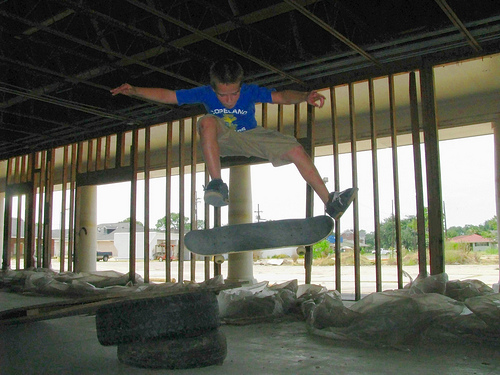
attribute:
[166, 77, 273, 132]
t-shirt — blue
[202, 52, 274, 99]
hair — short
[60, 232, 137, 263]
truck — parked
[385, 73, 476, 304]
stud — wooden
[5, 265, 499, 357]
sheeting — plastic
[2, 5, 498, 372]
building — unfinished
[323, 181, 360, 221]
shoe — grey, white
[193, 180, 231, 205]
shoe — white, grey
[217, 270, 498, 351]
plastic — bunched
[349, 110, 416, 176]
ground — outstretched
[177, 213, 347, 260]
skate board — in air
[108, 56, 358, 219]
skateboarder — in the air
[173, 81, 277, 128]
t-shirt — blue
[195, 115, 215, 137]
knee — skinned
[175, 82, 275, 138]
horse — deep blue, printed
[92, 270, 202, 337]
tire — black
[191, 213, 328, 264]
skateboard — grey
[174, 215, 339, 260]
skateboard — black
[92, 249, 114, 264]
pickup truck — blue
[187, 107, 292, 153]
shorts — khaki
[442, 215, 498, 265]
roof — red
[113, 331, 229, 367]
tire — black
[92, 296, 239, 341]
tire — black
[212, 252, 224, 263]
wheel — white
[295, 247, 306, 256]
wheel — white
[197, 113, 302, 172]
shorts — tan, khaki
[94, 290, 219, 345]
tire — old, rubber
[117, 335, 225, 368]
tire — old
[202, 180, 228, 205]
shoe — black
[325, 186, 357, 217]
shoe — black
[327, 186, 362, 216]
shoe — grey, white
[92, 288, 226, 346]
tire — black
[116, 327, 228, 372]
tire — black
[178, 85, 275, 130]
t-shirt — short sleeve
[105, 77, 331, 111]
arms — boy's